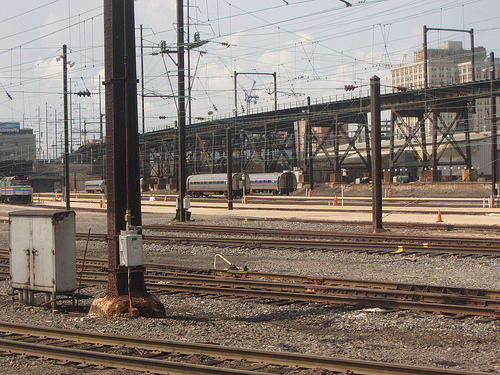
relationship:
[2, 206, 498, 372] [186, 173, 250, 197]
tracks for a passenger car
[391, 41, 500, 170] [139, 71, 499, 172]
building beyond bridge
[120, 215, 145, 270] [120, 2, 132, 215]
meter on a pole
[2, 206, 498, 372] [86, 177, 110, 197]
tracks for a train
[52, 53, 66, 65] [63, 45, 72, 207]
spool insulator on a pole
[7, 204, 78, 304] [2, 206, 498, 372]
utility box by tracks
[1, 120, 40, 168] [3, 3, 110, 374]
building on left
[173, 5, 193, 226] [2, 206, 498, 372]
eletrical post on tracks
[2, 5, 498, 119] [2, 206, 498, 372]
power lines onver tracks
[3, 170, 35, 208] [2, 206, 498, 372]
train engine on tracks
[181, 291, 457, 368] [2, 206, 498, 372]
stones between tracks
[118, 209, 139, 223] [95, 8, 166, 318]
post clamp on a pole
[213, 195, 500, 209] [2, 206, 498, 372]
guard rail divides tracks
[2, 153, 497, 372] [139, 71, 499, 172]
train yard below a bridge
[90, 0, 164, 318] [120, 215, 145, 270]
pole with meter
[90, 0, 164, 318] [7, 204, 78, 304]
pole besides a utility box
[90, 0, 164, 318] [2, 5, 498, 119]
pole for holing power lines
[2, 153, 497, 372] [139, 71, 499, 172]
train yard by a bridge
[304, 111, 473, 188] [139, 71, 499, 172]
trestle supports on bridge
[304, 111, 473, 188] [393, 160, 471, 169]
trestle supports have multiple sills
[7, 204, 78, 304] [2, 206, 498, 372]
utility box next to tracks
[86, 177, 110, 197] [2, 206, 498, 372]
train on tracks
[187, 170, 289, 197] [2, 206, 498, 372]
passenger car on tracks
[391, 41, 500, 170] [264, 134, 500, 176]
building beyond bridge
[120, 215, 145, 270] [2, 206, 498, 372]
meter by tracks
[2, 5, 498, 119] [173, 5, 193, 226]
power lines connected to eletrical post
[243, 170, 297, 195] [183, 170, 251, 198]
train car beside train car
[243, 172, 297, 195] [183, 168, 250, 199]
train car in front of train car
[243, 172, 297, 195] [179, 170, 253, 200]
train car behind train car